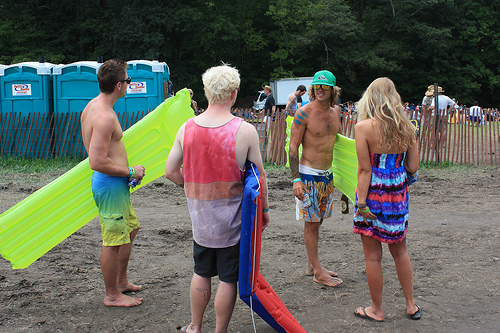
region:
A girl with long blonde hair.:
[355, 70, 422, 245]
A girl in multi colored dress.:
[349, 110, 421, 257]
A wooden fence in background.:
[423, 103, 496, 167]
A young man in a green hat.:
[301, 65, 348, 105]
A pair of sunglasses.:
[306, 72, 344, 102]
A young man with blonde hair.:
[197, 60, 257, 119]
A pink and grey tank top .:
[178, 97, 247, 250]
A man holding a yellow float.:
[44, 71, 164, 283]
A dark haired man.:
[80, 57, 142, 110]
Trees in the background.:
[284, 4, 488, 69]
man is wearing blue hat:
[310, 68, 338, 88]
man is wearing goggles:
[312, 83, 330, 91]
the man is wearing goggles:
[117, 76, 132, 84]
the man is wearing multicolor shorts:
[90, 166, 145, 251]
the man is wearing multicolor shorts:
[295, 170, 339, 225]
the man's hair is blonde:
[197, 63, 237, 106]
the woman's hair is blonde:
[355, 74, 412, 151]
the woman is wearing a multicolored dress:
[355, 146, 417, 244]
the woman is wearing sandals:
[352, 302, 425, 322]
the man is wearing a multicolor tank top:
[180, 115, 252, 253]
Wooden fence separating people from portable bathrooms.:
[1, 111, 498, 166]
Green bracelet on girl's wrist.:
[348, 208, 372, 215]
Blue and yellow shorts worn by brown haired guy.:
[93, 170, 138, 246]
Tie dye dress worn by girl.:
[364, 145, 411, 238]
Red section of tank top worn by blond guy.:
[182, 117, 242, 179]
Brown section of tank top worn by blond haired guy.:
[182, 179, 244, 199]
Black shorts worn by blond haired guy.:
[191, 241, 239, 281]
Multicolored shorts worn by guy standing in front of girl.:
[299, 166, 334, 223]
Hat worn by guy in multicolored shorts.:
[308, 65, 335, 87]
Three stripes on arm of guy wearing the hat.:
[291, 106, 309, 128]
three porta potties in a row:
[0, 55, 175, 159]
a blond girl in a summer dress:
[349, 76, 426, 322]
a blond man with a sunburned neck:
[159, 65, 265, 332]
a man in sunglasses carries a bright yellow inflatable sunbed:
[1, 57, 201, 309]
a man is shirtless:
[284, 67, 346, 289]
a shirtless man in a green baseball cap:
[288, 68, 350, 290]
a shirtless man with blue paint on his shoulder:
[284, 70, 347, 288]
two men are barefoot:
[74, 56, 346, 307]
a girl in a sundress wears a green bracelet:
[349, 76, 429, 323]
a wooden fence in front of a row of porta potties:
[0, 107, 495, 172]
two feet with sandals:
[349, 292, 431, 327]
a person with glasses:
[91, 56, 138, 108]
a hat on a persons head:
[304, 67, 344, 104]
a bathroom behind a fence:
[3, 51, 58, 168]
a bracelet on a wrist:
[288, 171, 306, 189]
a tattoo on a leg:
[188, 281, 217, 312]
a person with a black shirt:
[258, 79, 280, 122]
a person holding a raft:
[11, 53, 178, 311]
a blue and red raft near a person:
[219, 147, 314, 328]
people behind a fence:
[423, 76, 493, 173]